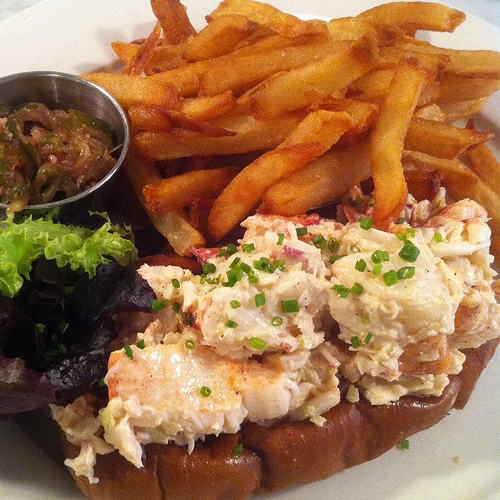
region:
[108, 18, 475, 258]
a plate iwth food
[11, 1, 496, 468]
a white plate with food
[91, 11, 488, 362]
food on a plate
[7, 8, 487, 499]
food on a white plate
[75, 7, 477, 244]
fries on a plate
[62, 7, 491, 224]
fries on a white plate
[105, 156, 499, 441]
green onions on the plate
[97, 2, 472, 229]
french fries on the plate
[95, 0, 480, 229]
the french fries are golden brown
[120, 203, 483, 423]
the salad is white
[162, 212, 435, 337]
green garnish on the salad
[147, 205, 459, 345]
the garnish is chives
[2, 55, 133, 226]
a small cup on the plate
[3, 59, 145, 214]
the cup is silver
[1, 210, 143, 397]
green and purple lettuce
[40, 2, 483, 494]
the plate is white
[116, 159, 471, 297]
Fries on the plate.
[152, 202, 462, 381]
Green onions on the food.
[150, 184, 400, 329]
Bacon on the food.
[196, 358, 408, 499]
Crust on the bread.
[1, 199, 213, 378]
Lettuce on the bread.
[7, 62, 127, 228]
Silver container on the plate.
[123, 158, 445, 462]
Chicken salad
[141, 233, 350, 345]
Green colored onions.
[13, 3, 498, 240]
Fries are in the shot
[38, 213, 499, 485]
This food is stuffed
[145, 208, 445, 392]
Green sprinkles on the food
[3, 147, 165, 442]
Lettuce in the shot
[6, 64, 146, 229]
This is a silver cup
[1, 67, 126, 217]
Vegetables in the cup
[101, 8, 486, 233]
Fries are cooked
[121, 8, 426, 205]
a side of french fries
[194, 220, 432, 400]
a bit of chicken salad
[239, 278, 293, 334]
a bunch of green chives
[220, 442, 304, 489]
the crust of some bread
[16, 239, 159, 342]
a piece of green garnish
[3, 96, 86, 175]
some kind of brown sauce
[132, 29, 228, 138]
the brown burned bits of fries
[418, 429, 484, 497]
a white ceramic plate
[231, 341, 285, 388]
the browning of some chicken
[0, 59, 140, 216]
a container of peppers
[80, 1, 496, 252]
delicious looking french fries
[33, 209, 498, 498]
a big pile of food and toppings on a bun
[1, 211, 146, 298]
a green leafy vegetable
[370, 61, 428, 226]
the fry is orange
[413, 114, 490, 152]
the fry is orange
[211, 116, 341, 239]
the fry is orange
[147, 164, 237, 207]
the fry is orange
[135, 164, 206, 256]
the fry is orange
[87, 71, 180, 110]
the fry is orange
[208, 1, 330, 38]
the fry is orange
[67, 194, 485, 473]
the tuna is pink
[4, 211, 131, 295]
the lettuce is green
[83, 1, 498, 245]
golden french fries